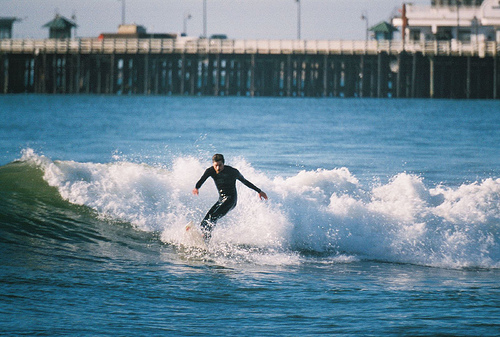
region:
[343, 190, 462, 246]
white waves in water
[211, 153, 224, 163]
hair on the man's head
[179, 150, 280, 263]
man surfing in water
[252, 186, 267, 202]
the man's left hand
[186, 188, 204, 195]
the man's right hand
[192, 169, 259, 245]
black wet suit worn by man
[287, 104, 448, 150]
the calm blue body of water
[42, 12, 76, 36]
green shelter on land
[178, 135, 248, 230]
surfer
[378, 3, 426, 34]
white clouds in blue sky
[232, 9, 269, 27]
white clouds in blue sky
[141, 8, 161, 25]
white clouds in blue sky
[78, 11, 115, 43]
white clouds in blue sky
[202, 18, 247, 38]
white clouds in blue sky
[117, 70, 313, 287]
the man is surfing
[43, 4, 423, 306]
surfing by the pier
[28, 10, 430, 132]
a white fence on pier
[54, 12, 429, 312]
the surfer is by the pier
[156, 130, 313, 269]
surfer cresting a wave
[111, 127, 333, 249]
the waves are white capped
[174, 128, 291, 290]
the hair is black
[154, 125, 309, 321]
the surfer is male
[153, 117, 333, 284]
the sport is surfing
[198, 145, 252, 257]
surfer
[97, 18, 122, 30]
white clouds in blue sky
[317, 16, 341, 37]
white clouds in blue sky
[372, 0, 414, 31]
white clouds in blue sky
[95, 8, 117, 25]
white clouds in blue sky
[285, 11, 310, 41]
white clouds in blue sky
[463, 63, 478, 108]
wooden pillar on pier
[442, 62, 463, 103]
wooden pillar on pier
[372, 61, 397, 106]
wooden pillar on pier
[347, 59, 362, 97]
wooden pillar on pier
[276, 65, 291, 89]
wooden pillar on pier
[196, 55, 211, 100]
wooden pillar on pier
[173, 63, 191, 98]
wooden pillar on pier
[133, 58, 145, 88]
wooden pillar on pier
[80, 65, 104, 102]
wooden pillar on pier